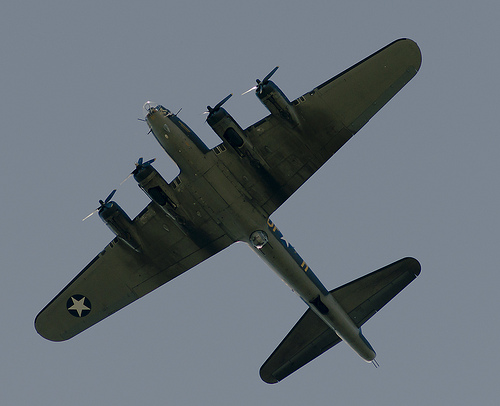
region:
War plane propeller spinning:
[81, 181, 133, 231]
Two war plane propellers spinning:
[66, 143, 179, 236]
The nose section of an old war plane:
[128, 93, 192, 144]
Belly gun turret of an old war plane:
[242, 218, 281, 262]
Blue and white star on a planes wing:
[59, 288, 109, 330]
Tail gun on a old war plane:
[351, 335, 391, 380]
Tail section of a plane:
[245, 241, 456, 387]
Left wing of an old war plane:
[209, 29, 463, 242]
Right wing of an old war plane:
[5, 153, 214, 346]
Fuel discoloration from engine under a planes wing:
[234, 141, 296, 213]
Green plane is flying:
[18, 65, 433, 386]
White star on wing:
[56, 295, 93, 319]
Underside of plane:
[191, 161, 347, 328]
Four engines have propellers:
[100, 68, 300, 263]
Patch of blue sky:
[5, 72, 105, 205]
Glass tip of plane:
[134, 93, 165, 120]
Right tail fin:
[231, 313, 376, 382]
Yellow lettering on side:
[265, 215, 319, 280]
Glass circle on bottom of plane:
[248, 223, 277, 254]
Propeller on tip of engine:
[119, 150, 155, 185]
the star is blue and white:
[60, 289, 102, 325]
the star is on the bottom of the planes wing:
[58, 291, 98, 323]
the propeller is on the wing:
[73, 183, 153, 270]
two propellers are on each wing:
[54, 159, 209, 281]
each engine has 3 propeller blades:
[74, 187, 124, 227]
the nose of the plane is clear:
[130, 96, 165, 125]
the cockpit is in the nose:
[136, 97, 163, 119]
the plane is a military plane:
[22, 14, 441, 399]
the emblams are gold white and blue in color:
[230, 182, 335, 295]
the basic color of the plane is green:
[20, 35, 459, 382]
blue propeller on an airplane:
[79, 190, 127, 214]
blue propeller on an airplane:
[119, 152, 158, 175]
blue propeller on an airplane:
[196, 92, 233, 114]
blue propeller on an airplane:
[231, 63, 296, 98]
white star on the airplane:
[64, 293, 96, 319]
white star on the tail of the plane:
[282, 231, 289, 248]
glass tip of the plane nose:
[137, 92, 161, 113]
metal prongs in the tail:
[366, 353, 379, 368]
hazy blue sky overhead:
[23, 16, 303, 72]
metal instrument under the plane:
[251, 230, 271, 246]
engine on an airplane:
[76, 188, 169, 268]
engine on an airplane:
[113, 150, 204, 241]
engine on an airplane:
[194, 85, 279, 179]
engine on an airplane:
[235, 64, 320, 144]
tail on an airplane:
[240, 233, 444, 390]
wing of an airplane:
[196, 27, 431, 214]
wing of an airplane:
[17, 162, 230, 354]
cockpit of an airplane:
[130, 95, 176, 136]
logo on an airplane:
[62, 291, 92, 321]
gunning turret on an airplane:
[244, 226, 277, 258]